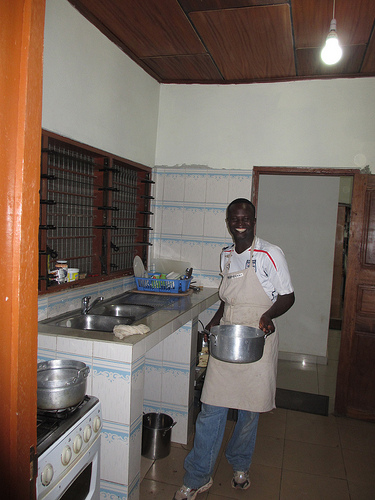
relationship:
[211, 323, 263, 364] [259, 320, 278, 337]
pan in hand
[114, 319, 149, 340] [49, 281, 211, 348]
towel on counter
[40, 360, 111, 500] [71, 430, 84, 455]
stove has knob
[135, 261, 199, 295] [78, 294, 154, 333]
tray on sink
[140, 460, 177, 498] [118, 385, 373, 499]
rug on floor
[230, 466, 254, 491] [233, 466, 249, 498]
shoe on foot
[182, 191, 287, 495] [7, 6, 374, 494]
cook in kitchen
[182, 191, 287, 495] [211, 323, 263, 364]
cook holding pan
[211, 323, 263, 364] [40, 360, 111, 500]
pan on stove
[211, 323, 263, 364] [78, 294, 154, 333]
pan on sink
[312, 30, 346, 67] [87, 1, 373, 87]
lightbulb on ceiling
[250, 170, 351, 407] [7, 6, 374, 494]
doorway to kitchen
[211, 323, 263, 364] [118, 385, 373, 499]
pan on floor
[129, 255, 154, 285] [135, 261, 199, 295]
plate in tray